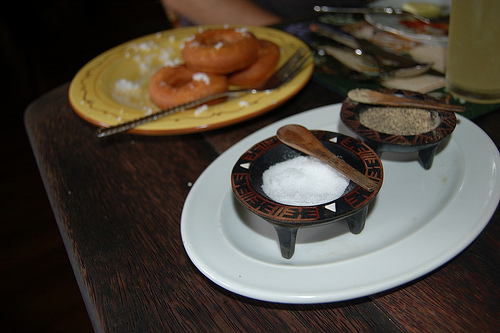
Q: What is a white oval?
A: Plate.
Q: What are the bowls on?
A: The white plate.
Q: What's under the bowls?
A: The white plate.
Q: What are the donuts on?
A: The yellow plate.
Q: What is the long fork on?
A: The yellow plate.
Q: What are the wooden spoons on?
A: The bowls.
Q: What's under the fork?
A: The yellow plate.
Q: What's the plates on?
A: The table.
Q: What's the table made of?
A: Wood.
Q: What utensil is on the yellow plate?
A: A fork.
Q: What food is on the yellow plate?
A: Donuts.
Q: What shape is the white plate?
A: Oval.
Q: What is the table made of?
A: Wood.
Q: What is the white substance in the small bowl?
A: Salt.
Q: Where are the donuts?
A: On the yellow plate.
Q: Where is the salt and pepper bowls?
A: On the white plate.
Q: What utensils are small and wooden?
A: Spoons.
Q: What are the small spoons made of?
A: Wood.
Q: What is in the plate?
A: Fork.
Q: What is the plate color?
A: White.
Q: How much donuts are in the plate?
A: Three mini.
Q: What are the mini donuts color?
A: Brown.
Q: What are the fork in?
A: A plate.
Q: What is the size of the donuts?
A: Mini brown.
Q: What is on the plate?
A: Donuts.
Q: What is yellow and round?
A: The plate.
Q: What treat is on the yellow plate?
A: Donuts.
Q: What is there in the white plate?
A: Salt and pepper.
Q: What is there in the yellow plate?
A: Donuts.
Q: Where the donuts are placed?
A: On yellow plate.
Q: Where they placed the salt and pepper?
A: On white plate.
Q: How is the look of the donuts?
A: Good.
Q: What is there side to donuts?
A: Fork.